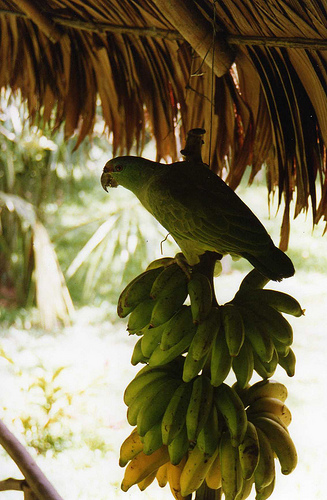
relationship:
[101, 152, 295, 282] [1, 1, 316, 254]
bird under hut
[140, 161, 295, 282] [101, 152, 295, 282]
feathers on bird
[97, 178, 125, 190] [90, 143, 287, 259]
beak on parrot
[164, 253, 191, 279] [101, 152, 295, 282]
foot on bird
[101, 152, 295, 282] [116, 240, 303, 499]
bird on bananas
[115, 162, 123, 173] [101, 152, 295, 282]
eye on bird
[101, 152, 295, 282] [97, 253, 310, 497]
bird on bananas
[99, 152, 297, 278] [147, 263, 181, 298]
bird standing on banana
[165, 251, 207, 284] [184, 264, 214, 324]
foot on banana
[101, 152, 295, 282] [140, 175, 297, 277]
bird has feathers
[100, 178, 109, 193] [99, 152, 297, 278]
beak of bird